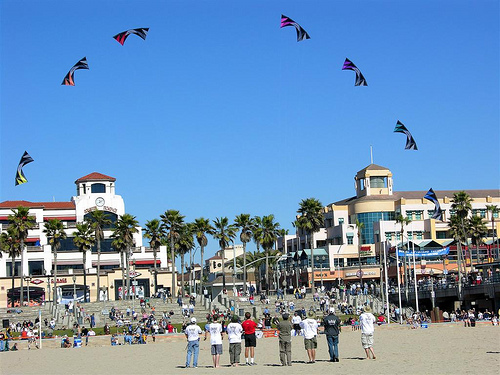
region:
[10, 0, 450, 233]
kites being flown in semi-circular formation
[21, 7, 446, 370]
people standing on sand and controlling kites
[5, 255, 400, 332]
wide stairs leading up to shops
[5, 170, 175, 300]
large red and white building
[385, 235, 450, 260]
long blue and white banner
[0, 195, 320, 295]
row of palm trees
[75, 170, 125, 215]
clock on exterior of building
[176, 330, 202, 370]
man wearing blue jeans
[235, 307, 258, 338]
man wearing a red shirt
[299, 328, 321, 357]
man wearing green shorts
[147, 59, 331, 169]
this is the sky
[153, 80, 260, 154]
the sky is blue in color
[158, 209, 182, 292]
this is a tree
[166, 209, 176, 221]
the tree has green leaves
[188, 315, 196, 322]
this is a cap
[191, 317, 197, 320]
the cap is white in color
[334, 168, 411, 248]
this is a building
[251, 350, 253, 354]
the man is light skinned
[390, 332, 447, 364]
this is the ground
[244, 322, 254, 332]
this is a red t shirt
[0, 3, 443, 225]
a semicircle of colorful kites in the air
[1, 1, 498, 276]
a cloudless sky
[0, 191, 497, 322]
a human-created city forest of palm trees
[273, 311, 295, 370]
man wears a khaki outfit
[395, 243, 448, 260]
blue banner with illegible white printing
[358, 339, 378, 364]
man in shorts has one bent knee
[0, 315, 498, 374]
we are near the sea because people stand on sand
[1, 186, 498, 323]
many shops in the background make up an outdoor mall; their signs are illegible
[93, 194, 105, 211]
a clock in a red & white building's small tower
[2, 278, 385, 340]
people walk, sit, stand, & lay on steps leading to the sand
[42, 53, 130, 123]
Kite in the sky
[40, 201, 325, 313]
Trees by a street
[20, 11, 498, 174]
Kites in the sky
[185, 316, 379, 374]
Men watching kites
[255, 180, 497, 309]
Brown and blue building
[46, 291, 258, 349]
Stairs with people on them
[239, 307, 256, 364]
Boy wearing red shirt and black shorts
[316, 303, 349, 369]
Man in gray shirt and jeans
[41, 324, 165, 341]
Grass with people on it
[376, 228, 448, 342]
Light poles by a beach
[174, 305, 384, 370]
Eight people looking at the scenario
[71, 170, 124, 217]
A clock tower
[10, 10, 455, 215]
Colorful flags in an arch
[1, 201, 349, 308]
Palm trees bordering the street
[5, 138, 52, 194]
A yellow and blue flag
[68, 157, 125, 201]
A white tower with a red roof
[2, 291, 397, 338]
Steps with many people on them.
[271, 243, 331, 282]
Building with green roofs.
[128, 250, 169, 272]
A red awning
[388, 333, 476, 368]
A sandy surface